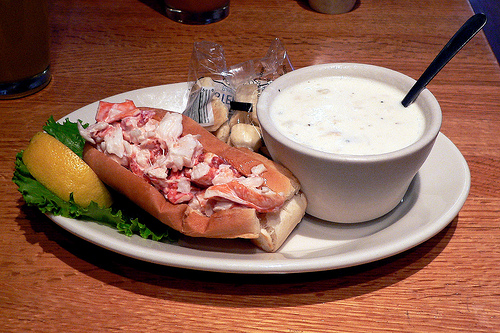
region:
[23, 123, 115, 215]
a lemon wedge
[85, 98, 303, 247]
a lobster sandwich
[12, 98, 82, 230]
a leaf of lettuce with a lemon wedge on it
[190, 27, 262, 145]
crackers in a plastic casing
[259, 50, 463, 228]
a bowl of soup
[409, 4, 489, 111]
the top of a spoon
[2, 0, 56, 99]
part of a glass on a table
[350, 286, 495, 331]
the top of a wooden table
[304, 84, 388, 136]
new England clam chowder soup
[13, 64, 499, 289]
a white plate with a sandwich, bowl of soup, crackers, lettuce, and a lemon wedge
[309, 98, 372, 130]
soup in white cup.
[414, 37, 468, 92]
spoon in soup cup.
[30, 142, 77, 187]
lemon wedge on lettuce.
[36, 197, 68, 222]
green lettuce on plate.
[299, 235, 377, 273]
white plate on the table.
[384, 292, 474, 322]
table made of wood.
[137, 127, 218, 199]
sandwich on the plate.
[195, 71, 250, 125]
crackers in a package.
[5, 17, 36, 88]
glass on the table.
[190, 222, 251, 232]
bread holding sandwich ingredients.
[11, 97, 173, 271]
a slice of green lettuce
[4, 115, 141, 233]
a slice of lemon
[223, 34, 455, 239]
a bowl with white liquid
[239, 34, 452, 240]
white sauce in a bowl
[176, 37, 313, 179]
a bag of oyster crackers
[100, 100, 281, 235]
pulled pork that is pink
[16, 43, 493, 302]
a very round white plate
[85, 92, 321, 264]
a bun filled with meat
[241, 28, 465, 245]
white gravy in a bowl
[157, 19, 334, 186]
a bag on a plate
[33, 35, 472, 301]
white plate with food on it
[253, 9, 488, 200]
silver utensil for eating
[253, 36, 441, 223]
white bowl for serving food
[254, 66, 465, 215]
bowl of white soup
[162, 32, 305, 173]
package of oyster crackers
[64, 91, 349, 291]
white bread roll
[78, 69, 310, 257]
large lobster roll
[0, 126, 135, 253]
slice of yellow lemon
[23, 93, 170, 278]
green lettuce garnish under the lemon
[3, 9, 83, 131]
beverage in a glass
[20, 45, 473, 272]
Renowned New England dinner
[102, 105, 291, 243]
Lobster chunks hot dog bun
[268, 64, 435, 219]
New England Clam Chowder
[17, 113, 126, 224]
Wedge lemon garnish lobster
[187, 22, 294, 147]
Cellophane package oyster crackers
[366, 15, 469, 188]
Spoon submerged in chowder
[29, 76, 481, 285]
White plate holds meal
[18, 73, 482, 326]
Plate sits wood table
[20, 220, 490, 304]
Shadow formed overhead lighting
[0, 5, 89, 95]
Water glass customer drink